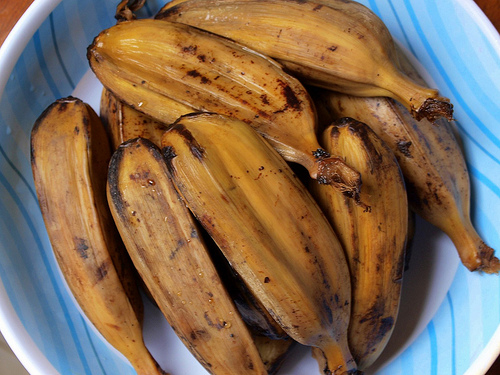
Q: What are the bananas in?
A: Bowl.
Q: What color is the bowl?
A: Blue and white.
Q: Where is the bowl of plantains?
A: Table.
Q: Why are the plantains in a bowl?
A: Contain them.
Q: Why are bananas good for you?
A: Potassium.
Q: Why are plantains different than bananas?
A: The taste.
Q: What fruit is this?
A: Bananas.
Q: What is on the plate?
A: Bananas.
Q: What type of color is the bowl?
A: Blue.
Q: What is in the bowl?
A: Plantains.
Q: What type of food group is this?
A: Fruit.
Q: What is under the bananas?
A: A bowl.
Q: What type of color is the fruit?
A: Golden brown.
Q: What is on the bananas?
A: Black spots.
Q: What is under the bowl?
A: Table.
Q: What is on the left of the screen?
A: Two green stripes.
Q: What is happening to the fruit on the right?
A: Stems decaying.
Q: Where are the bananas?
A: Plate.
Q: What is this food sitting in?
A: A bowl.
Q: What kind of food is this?
A: Plantains.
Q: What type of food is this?
A: Fruit.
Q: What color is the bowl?
A: Blue.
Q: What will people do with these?
A: Eat them.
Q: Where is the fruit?
A: Inside the peels.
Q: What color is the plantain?
A: Yellow.